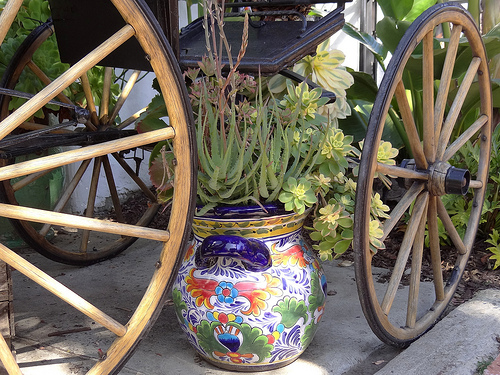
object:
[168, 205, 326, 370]
pot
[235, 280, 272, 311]
flower decorations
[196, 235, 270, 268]
handle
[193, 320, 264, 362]
flower decorations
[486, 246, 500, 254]
leaves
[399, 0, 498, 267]
garden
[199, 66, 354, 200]
plant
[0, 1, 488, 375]
cart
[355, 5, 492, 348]
wheel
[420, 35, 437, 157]
spokes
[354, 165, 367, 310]
tire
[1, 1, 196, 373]
wheel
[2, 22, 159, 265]
wheel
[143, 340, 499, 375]
floor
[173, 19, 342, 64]
seat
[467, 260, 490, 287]
mulch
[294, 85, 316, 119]
flower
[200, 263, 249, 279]
flower decorations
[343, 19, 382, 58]
leaves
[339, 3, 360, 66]
wall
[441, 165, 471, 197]
knob